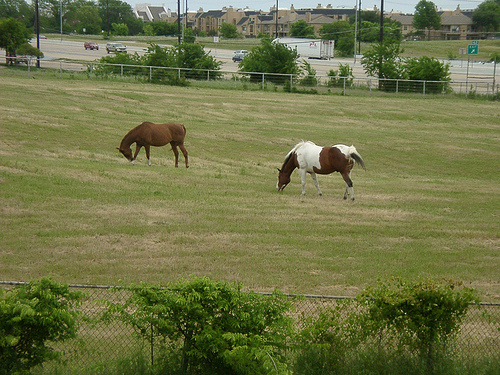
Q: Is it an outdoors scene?
A: Yes, it is outdoors.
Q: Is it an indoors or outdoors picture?
A: It is outdoors.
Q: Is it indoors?
A: No, it is outdoors.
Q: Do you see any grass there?
A: Yes, there is grass.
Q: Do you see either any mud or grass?
A: Yes, there is grass.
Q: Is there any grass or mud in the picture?
A: Yes, there is grass.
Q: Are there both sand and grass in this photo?
A: No, there is grass but no sand.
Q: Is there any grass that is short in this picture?
A: Yes, there is short grass.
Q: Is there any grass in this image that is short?
A: Yes, there is grass that is short.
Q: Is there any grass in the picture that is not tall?
A: Yes, there is short grass.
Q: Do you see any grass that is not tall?
A: Yes, there is short grass.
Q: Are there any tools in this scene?
A: No, there are no tools.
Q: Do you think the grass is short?
A: Yes, the grass is short.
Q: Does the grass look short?
A: Yes, the grass is short.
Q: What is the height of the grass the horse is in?
A: The grass is short.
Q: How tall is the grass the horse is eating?
A: The grass is short.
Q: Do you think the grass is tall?
A: No, the grass is short.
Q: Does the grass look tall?
A: No, the grass is short.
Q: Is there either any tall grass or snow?
A: No, there is grass but it is short.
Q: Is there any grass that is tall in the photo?
A: No, there is grass but it is short.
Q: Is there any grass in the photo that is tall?
A: No, there is grass but it is short.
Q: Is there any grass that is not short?
A: No, there is grass but it is short.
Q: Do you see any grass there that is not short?
A: No, there is grass but it is short.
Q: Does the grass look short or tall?
A: The grass is short.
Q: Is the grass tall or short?
A: The grass is short.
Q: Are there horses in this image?
A: Yes, there is a horse.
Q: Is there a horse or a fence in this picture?
A: Yes, there is a horse.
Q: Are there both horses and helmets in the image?
A: No, there is a horse but no helmets.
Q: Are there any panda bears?
A: No, there are no panda bears.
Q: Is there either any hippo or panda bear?
A: No, there are no panda bears or hippoes.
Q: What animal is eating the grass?
A: The horse is eating the grass.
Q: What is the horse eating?
A: The horse is eating grass.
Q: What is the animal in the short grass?
A: The animal is a horse.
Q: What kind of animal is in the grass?
A: The animal is a horse.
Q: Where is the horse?
A: The horse is in the grass.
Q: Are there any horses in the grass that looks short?
A: Yes, there is a horse in the grass.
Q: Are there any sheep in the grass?
A: No, there is a horse in the grass.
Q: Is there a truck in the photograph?
A: Yes, there is a truck.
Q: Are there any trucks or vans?
A: Yes, there is a truck.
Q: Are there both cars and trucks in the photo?
A: Yes, there are both a truck and a car.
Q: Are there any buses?
A: No, there are no buses.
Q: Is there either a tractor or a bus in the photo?
A: No, there are no buses or tractors.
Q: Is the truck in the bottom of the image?
A: No, the truck is in the top of the image.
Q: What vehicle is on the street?
A: The vehicle is a truck.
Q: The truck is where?
A: The truck is on the street.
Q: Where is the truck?
A: The truck is on the street.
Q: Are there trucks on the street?
A: Yes, there is a truck on the street.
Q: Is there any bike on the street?
A: No, there is a truck on the street.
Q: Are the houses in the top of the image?
A: Yes, the houses are in the top of the image.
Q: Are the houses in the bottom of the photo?
A: No, the houses are in the top of the image.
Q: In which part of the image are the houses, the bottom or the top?
A: The houses are in the top of the image.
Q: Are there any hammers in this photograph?
A: No, there are no hammers.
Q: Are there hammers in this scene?
A: No, there are no hammers.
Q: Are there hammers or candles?
A: No, there are no hammers or candles.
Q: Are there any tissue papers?
A: No, there are no tissue papers.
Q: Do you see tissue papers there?
A: No, there are no tissue papers.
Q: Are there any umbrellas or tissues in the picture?
A: No, there are no tissues or umbrellas.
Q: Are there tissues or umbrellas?
A: No, there are no tissues or umbrellas.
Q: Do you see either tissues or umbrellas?
A: No, there are no tissues or umbrellas.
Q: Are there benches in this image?
A: No, there are no benches.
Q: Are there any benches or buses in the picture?
A: No, there are no benches or buses.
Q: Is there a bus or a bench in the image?
A: No, there are no benches or buses.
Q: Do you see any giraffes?
A: No, there are no giraffes.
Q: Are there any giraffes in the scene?
A: No, there are no giraffes.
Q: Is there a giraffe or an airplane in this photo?
A: No, there are no giraffes or airplanes.